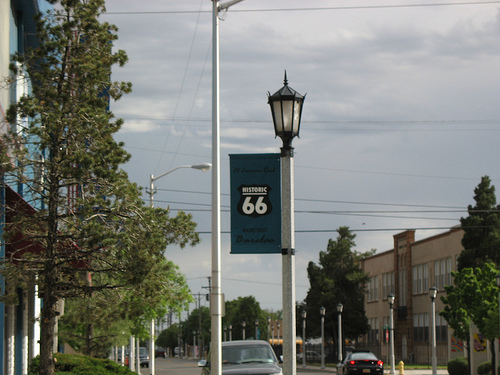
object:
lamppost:
[266, 68, 308, 375]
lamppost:
[429, 285, 438, 374]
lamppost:
[387, 291, 397, 373]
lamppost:
[338, 301, 344, 361]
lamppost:
[320, 306, 327, 368]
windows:
[430, 255, 460, 292]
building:
[356, 224, 498, 364]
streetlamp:
[428, 283, 438, 301]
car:
[337, 349, 384, 374]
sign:
[228, 153, 283, 254]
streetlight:
[387, 295, 396, 306]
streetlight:
[337, 302, 345, 314]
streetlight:
[320, 305, 327, 318]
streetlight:
[301, 311, 308, 319]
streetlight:
[266, 316, 274, 324]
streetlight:
[241, 320, 247, 327]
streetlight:
[255, 320, 259, 327]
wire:
[140, 185, 467, 210]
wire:
[142, 196, 457, 219]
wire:
[167, 206, 467, 212]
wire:
[193, 225, 452, 235]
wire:
[123, 143, 498, 183]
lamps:
[266, 69, 308, 156]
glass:
[281, 99, 293, 132]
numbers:
[242, 196, 268, 215]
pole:
[212, 1, 224, 373]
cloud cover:
[36, 1, 498, 334]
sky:
[34, 1, 332, 91]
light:
[255, 319, 260, 327]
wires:
[147, 189, 465, 238]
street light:
[243, 321, 248, 329]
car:
[124, 346, 151, 369]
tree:
[0, 0, 202, 373]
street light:
[150, 163, 211, 375]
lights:
[350, 359, 356, 363]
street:
[136, 351, 344, 375]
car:
[203, 338, 284, 374]